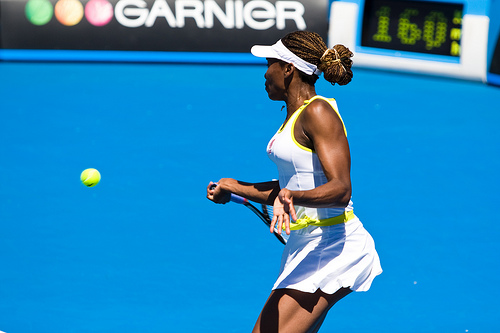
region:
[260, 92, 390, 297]
Woman wearing a dress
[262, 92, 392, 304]
Woman is wearing a dress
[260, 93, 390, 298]
Woman wearing a white and yellow dress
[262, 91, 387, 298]
Woman is wearing a white and yellow dress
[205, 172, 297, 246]
Woman holding a tennis racket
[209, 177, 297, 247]
Woman is holding a tennis racket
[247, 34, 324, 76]
Woman wearing a hat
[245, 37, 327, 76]
Woman is wearing a hat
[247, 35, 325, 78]
Woman wearing a visor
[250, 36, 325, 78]
Woman is wearing a visor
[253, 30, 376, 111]
the head of a woman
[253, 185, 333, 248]
the hand of a woman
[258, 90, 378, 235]
the arm of a woman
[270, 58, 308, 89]
the ear of a woman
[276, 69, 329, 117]
the neck of a woman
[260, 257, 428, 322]
the leg of a woman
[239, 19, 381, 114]
the hair of a woman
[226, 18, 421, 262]
a woman wearing a hat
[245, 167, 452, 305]
a woman wearing a skirt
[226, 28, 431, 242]
a woman wearing a tanktop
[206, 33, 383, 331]
woman getting ready to hit the tennis ball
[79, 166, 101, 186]
yellow tennis ball in the air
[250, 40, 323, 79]
white visor cap worn by tennis player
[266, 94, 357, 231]
white tank top trimed in yellow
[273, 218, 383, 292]
white tennis skirt worn by tennis player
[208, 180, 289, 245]
tennis racket held by tennis player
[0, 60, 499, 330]
blue wall on the side of tennis player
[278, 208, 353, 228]
yellow trim of white tank top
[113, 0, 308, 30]
white print on a black background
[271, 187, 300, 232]
left hand of tennis player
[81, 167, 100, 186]
a tennis ball in the air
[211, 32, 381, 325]
a woman playing tennis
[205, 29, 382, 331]
a woman swinging a tennis racket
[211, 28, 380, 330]
a woman wearing a white tennis outfit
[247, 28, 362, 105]
a woman wearing a white visor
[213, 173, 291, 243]
the tennis racket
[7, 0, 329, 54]
a billboard sign in the back ground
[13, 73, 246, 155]
a blue wall behind the lady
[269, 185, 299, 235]
the hand of the woman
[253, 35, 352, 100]
a woman with her hair in a bun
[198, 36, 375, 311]
she is playing tennis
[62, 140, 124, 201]
the ball is in the air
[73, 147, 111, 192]
the ball is green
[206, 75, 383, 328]
her outfit is white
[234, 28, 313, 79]
her hat is white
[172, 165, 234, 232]
holding the racket in her right hand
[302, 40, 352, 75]
hair is in a bun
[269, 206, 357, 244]
her belt is yellow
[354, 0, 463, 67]
the text is green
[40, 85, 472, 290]
the wall is blue